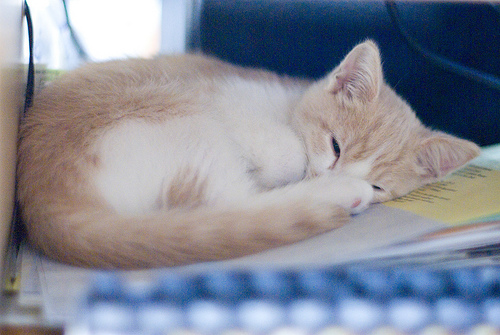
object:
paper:
[1, 142, 500, 325]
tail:
[18, 180, 352, 272]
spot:
[351, 198, 361, 208]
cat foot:
[330, 176, 374, 214]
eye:
[373, 185, 381, 189]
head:
[294, 39, 482, 205]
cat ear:
[416, 135, 481, 182]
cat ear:
[326, 37, 381, 104]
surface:
[0, 0, 500, 334]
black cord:
[21, 0, 35, 119]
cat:
[17, 37, 485, 272]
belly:
[69, 86, 258, 213]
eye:
[332, 137, 341, 158]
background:
[0, 0, 499, 334]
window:
[60, 0, 164, 61]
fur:
[14, 39, 483, 272]